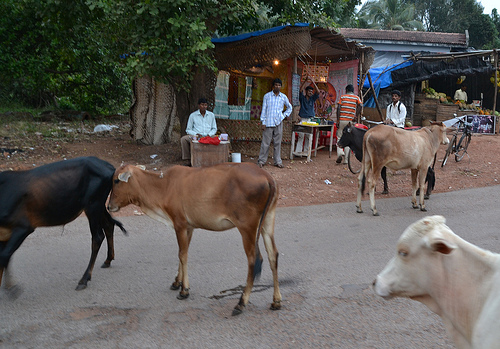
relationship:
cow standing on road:
[1, 154, 129, 302] [0, 184, 499, 348]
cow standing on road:
[106, 160, 282, 316] [0, 184, 499, 348]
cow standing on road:
[355, 121, 451, 218] [0, 184, 499, 348]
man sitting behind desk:
[178, 97, 218, 164] [190, 133, 230, 166]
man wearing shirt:
[256, 77, 293, 169] [260, 92, 294, 128]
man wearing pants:
[256, 77, 293, 169] [257, 121, 284, 167]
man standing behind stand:
[454, 83, 469, 104] [413, 85, 500, 134]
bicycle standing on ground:
[440, 113, 473, 168] [1, 118, 498, 216]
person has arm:
[294, 72, 322, 161] [298, 74, 309, 103]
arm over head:
[298, 74, 309, 103] [304, 85, 314, 96]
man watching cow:
[256, 77, 293, 169] [106, 160, 282, 316]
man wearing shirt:
[335, 84, 364, 167] [337, 93, 362, 123]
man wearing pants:
[335, 84, 364, 167] [336, 119, 355, 164]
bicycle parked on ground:
[440, 113, 473, 168] [1, 118, 498, 216]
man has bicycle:
[335, 84, 364, 167] [440, 113, 473, 168]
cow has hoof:
[106, 160, 282, 316] [176, 291, 188, 300]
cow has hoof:
[106, 160, 282, 316] [169, 283, 180, 290]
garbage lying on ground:
[93, 123, 117, 134] [1, 118, 498, 216]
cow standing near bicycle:
[355, 121, 451, 218] [440, 113, 473, 168]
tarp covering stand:
[389, 55, 494, 90] [413, 85, 500, 134]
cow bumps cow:
[106, 160, 282, 316] [1, 154, 129, 302]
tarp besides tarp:
[389, 55, 494, 90] [356, 61, 415, 110]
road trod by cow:
[0, 184, 499, 348] [1, 154, 129, 302]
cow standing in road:
[106, 160, 282, 316] [0, 184, 499, 348]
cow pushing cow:
[106, 160, 282, 316] [1, 154, 129, 302]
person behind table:
[294, 72, 322, 161] [289, 122, 334, 164]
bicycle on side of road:
[440, 113, 473, 168] [0, 184, 499, 348]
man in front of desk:
[178, 97, 218, 164] [190, 133, 230, 166]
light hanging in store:
[273, 59, 280, 66] [176, 20, 376, 159]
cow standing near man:
[355, 121, 451, 218] [335, 84, 364, 167]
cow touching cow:
[106, 160, 282, 316] [1, 154, 129, 302]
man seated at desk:
[178, 97, 218, 164] [190, 133, 230, 166]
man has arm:
[256, 77, 293, 169] [284, 97, 293, 117]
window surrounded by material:
[227, 73, 248, 107] [213, 68, 254, 122]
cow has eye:
[371, 215, 500, 348] [398, 248, 409, 258]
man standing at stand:
[454, 83, 469, 104] [413, 85, 500, 134]